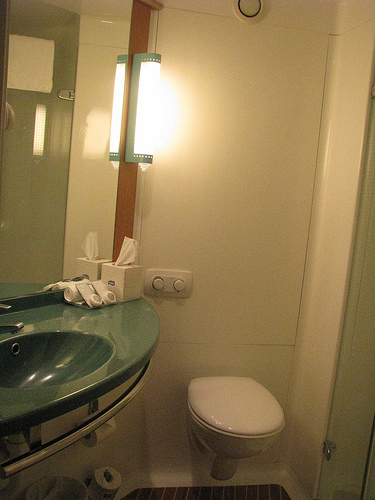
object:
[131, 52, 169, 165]
light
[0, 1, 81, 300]
mirror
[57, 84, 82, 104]
knobs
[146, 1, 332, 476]
wall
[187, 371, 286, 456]
toilet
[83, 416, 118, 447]
toilet paper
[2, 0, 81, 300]
door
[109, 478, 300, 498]
floor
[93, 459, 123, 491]
roll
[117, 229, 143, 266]
tissues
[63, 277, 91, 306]
towel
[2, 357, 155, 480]
rail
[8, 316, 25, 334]
faucet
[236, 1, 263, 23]
alarm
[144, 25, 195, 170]
vanity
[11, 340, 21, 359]
drain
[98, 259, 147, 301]
box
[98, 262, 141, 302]
dispenser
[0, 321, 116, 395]
sink